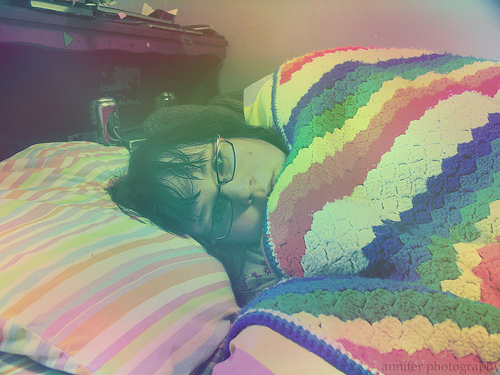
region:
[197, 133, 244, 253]
glasses on a girl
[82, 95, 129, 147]
can of soda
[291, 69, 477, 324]
colorful blanket covering girl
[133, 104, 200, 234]
brown hair on girl's head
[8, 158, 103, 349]
colorful striped pillow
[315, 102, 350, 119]
green part of blanket on girl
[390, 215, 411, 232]
blue part of blanket on girl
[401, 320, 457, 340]
yellow part of blanket on girl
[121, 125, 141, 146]
alarm clock on table beside bed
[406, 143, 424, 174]
white part of blanket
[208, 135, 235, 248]
eyeglasses on the woman's face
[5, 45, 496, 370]
a woman lying down in the bed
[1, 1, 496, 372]
a woman in the bed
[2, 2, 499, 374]
a bed and dresser in the bedroom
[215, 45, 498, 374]
a rainbow colored bedspread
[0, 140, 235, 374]
a pillow case with pastel stripped colors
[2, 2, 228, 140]
a wooden headboard to the bed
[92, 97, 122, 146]
an empty soda can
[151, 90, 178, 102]
the top of a soda can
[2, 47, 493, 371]
a woman resting in the bed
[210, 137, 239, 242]
Brown rimmed glasses on girl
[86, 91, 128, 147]
Cola can on headboard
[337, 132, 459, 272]
Multi colored afghan on bed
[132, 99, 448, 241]
Girl under multi colored afghan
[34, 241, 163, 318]
Multi colored striped pillowcase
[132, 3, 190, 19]
Paper on headboard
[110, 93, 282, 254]
Girl with head on pillow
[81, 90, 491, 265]
Girl in bed with afghan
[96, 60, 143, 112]
Picture on back of headboard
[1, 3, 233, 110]
Brown wood headboard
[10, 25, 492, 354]
a girl resting on the bed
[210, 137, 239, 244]
glasses with black frame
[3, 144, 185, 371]
a multicolor pillow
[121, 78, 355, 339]
a thoughtful girl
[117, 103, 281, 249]
a girl with black hair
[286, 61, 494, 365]
a multicolored bed sheet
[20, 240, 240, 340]
different color stripes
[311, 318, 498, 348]
a yellow stripe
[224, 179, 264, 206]
the nose of the girl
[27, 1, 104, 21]
a black cover notebook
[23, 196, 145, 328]
a pillow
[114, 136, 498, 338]
a person laying down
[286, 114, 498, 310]
a colorful blanket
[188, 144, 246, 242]
eye glasses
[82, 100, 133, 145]
a can on the headboard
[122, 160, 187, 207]
the person has black hair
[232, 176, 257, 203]
nose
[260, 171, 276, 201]
the persons lips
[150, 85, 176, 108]
a can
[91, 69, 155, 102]
a picture on the headboard